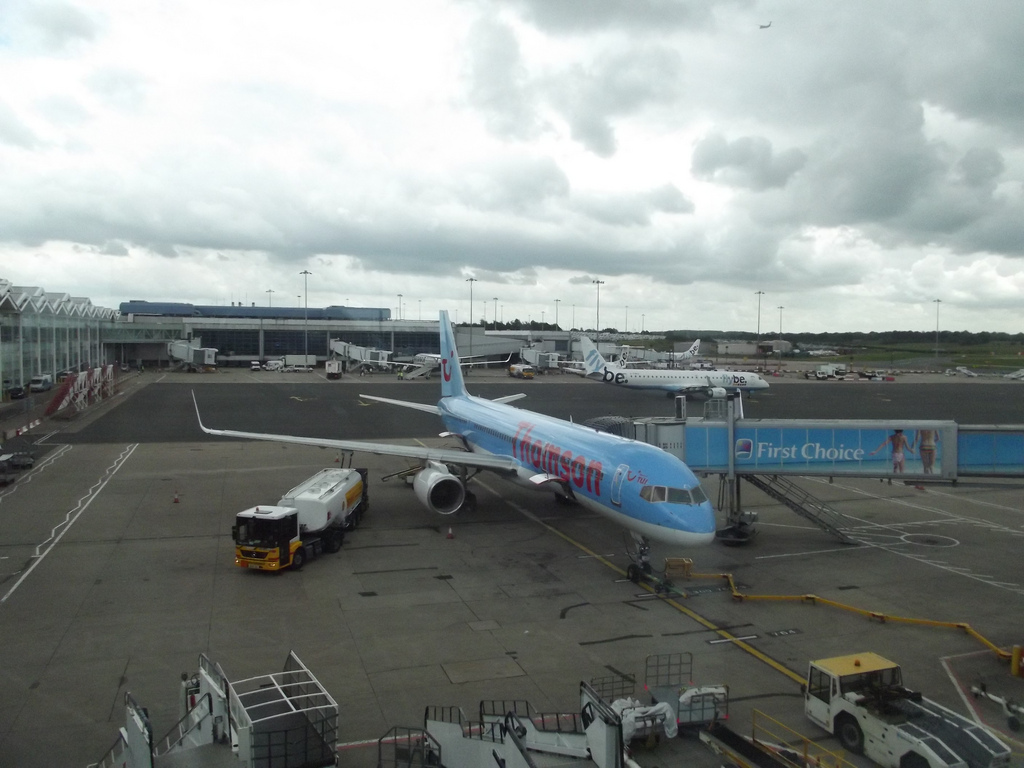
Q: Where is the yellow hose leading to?
A: The plain.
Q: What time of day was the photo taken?
A: Daytime.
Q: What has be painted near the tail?
A: The plain in the background.